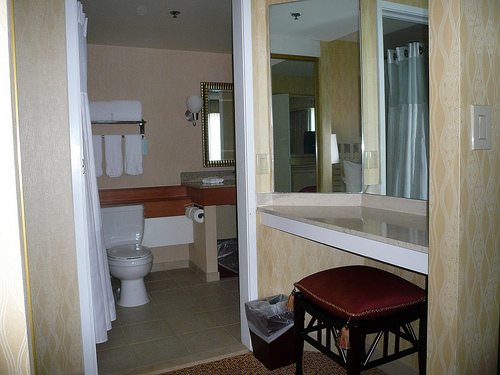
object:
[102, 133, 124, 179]
towel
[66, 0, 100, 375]
door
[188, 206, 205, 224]
toilet paper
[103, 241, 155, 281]
toilet bowl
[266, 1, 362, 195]
mirror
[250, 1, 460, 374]
wall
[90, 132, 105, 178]
towel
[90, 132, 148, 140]
rod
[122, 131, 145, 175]
towel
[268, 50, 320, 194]
reflection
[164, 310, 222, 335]
tile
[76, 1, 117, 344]
curtain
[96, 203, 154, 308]
toilet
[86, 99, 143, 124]
towels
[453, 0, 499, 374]
wall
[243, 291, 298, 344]
trash bag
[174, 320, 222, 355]
flooring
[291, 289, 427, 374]
stool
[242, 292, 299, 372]
trash can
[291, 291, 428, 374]
black stool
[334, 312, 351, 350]
tassel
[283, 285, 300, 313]
tassel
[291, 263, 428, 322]
pillow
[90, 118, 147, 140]
rack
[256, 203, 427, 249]
counter top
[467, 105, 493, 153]
light switch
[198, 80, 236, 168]
mirror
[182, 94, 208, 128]
light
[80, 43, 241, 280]
wall